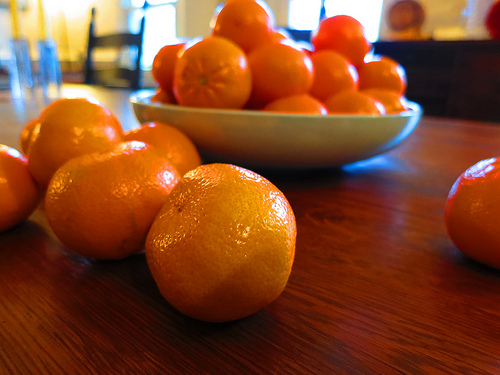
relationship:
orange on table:
[153, 165, 324, 331] [35, 81, 452, 362]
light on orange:
[242, 182, 323, 258] [38, 27, 496, 346]